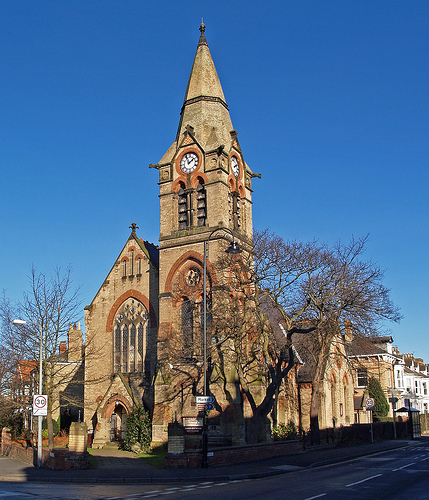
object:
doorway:
[106, 404, 132, 443]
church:
[80, 18, 393, 459]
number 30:
[33, 395, 46, 407]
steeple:
[198, 18, 205, 31]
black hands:
[185, 154, 196, 165]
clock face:
[179, 151, 201, 174]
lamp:
[7, 313, 49, 468]